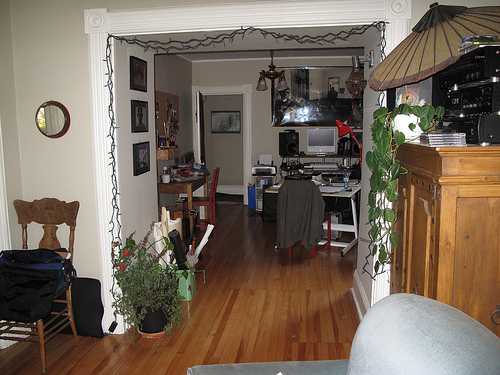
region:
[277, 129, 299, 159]
Black speaker on a desk.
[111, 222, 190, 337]
Plant sitting on the floor.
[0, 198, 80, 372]
Wooden chair sitting on a wooden floor.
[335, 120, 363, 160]
Red lamp over a desk.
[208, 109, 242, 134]
Picture hanging on a wall.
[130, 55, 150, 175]
Three pictures hanging on a wall.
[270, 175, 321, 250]
Coat hanging on the back of a red chair.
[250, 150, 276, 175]
Printer with paper coming out of the top.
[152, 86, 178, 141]
Bulletin board on the wall with stuff on it.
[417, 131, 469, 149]
Stack of cd's sitting on a brown hutch.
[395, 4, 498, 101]
tan and brown umbrella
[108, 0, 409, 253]
string of lights on the wall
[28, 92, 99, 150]
mirror on the wall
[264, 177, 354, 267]
jacket on the back of the chair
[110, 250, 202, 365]
flower plant on the flower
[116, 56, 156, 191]
pictures hanging on the wall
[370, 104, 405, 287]
plant hanging over the wall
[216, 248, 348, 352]
hardwood floors in the rooms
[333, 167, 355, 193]
water bottle on the desk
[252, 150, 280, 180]
printer next to doorway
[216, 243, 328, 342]
floor is hardwood is brown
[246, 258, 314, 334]
floor is hardwood is brown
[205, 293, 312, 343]
floor is hardwood is brown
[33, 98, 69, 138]
Circular mirror on the wall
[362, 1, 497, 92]
light brown paper umbrella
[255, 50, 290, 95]
hanging ceiling light fixture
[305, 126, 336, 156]
white colored computer monitor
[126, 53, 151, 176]
Three picture frames hanging on a wall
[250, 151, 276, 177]
printer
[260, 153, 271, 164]
white colored printer paper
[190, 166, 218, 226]
red wooden chair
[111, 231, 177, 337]
potted plant on the ground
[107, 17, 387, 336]
Hanging Christmas tree lights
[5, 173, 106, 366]
Old fashioned chair and table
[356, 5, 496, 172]
Hanging plant and umbrella decor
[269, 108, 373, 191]
Well-lit computer workstation area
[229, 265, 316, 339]
Well polished hardwood floors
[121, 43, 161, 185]
Triple stacked wall hangings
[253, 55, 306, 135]
Ornate ceiling fixture with globe lamps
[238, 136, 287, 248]
Single stand easy access printer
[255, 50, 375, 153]
Large hanging wall mirror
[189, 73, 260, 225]
Doorway entrance to vestibule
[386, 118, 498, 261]
Modular wood floor unit